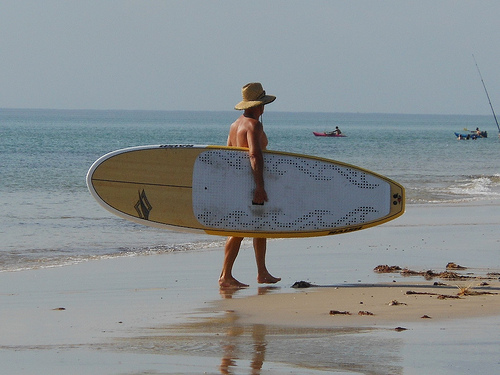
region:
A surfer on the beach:
[80, 70, 416, 300]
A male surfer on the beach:
[81, 56, 430, 298]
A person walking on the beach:
[81, 73, 413, 297]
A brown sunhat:
[225, 74, 282, 110]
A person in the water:
[309, 118, 347, 138]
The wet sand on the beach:
[16, 302, 232, 357]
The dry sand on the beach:
[310, 298, 454, 311]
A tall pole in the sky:
[466, 43, 498, 130]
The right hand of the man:
[249, 186, 272, 206]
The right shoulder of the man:
[241, 116, 267, 131]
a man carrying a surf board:
[82, 78, 413, 296]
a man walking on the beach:
[60, 80, 415, 292]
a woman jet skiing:
[306, 122, 352, 140]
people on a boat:
[445, 125, 493, 146]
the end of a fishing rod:
[466, 50, 495, 130]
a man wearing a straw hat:
[221, 81, 288, 123]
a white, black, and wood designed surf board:
[77, 137, 413, 239]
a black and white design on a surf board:
[196, 149, 379, 234]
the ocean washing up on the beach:
[11, 220, 163, 281]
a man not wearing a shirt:
[223, 80, 283, 167]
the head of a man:
[233, 78, 277, 120]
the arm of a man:
[242, 118, 268, 184]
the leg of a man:
[217, 226, 249, 277]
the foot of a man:
[213, 271, 253, 292]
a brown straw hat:
[228, 79, 280, 113]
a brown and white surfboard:
[80, 135, 411, 242]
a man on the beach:
[216, 75, 283, 295]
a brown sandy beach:
[1, 176, 499, 373]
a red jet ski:
[309, 121, 353, 144]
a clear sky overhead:
[1, 0, 498, 117]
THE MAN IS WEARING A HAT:
[228, 79, 284, 114]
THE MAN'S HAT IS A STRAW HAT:
[231, 80, 282, 115]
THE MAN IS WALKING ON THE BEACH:
[195, 80, 289, 308]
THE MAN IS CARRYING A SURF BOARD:
[78, 133, 413, 251]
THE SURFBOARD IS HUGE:
[80, 133, 412, 258]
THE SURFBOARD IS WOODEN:
[75, 138, 422, 255]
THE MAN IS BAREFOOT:
[208, 243, 291, 303]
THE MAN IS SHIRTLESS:
[211, 80, 291, 296]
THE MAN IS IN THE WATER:
[451, 118, 490, 151]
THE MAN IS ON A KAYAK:
[305, 115, 349, 145]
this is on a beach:
[19, 32, 418, 264]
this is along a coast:
[18, 33, 482, 270]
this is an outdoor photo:
[29, 61, 491, 313]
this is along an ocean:
[20, 64, 499, 326]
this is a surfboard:
[86, 133, 466, 253]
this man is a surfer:
[48, 65, 453, 317]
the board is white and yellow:
[81, 136, 490, 303]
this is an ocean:
[37, 97, 153, 177]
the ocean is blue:
[18, 107, 100, 164]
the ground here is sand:
[120, 272, 264, 355]